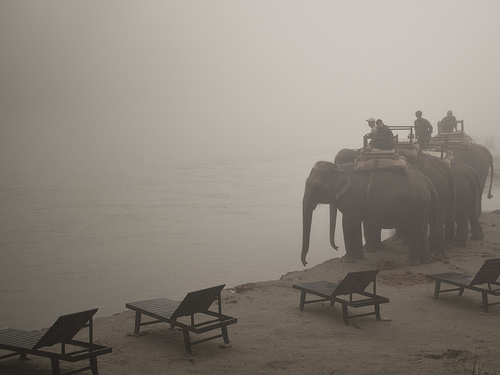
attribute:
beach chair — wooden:
[425, 259, 498, 313]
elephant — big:
[298, 154, 435, 266]